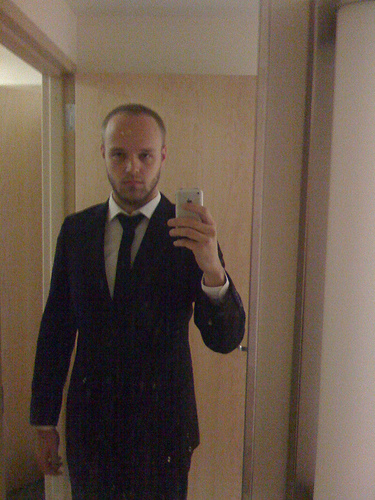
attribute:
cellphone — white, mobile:
[169, 188, 208, 243]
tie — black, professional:
[110, 210, 147, 300]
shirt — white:
[100, 192, 165, 304]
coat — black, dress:
[27, 188, 249, 466]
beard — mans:
[100, 174, 162, 205]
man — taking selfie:
[23, 94, 252, 499]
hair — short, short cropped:
[95, 102, 167, 153]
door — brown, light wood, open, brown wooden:
[62, 60, 264, 498]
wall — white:
[287, 5, 375, 495]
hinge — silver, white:
[62, 100, 79, 130]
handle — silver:
[233, 340, 248, 359]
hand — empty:
[29, 428, 67, 479]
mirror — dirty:
[1, 2, 374, 499]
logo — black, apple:
[184, 198, 194, 209]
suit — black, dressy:
[23, 190, 247, 499]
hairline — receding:
[113, 106, 156, 122]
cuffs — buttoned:
[230, 287, 244, 310]